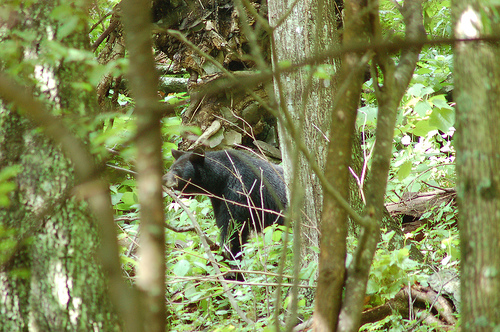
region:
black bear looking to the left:
[158, 137, 293, 267]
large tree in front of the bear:
[160, 3, 276, 149]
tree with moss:
[446, 1, 497, 327]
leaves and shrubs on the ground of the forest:
[10, 170, 455, 320]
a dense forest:
[15, 7, 481, 317]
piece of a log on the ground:
[336, 185, 491, 270]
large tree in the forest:
[267, 0, 424, 296]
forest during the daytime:
[11, 25, 475, 312]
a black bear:
[164, 138, 283, 252]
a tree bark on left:
[1, 20, 91, 330]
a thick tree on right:
[265, 0, 357, 330]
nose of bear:
[164, 172, 179, 187]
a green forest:
[1, 0, 496, 329]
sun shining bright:
[392, 3, 484, 199]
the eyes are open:
[176, 160, 188, 169]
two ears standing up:
[171, 144, 206, 159]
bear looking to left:
[162, 143, 287, 269]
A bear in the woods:
[162, 147, 264, 198]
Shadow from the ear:
[194, 156, 201, 160]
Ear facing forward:
[173, 150, 177, 156]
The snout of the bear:
[165, 174, 172, 183]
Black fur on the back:
[242, 161, 257, 174]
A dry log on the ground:
[404, 199, 423, 209]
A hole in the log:
[405, 216, 411, 221]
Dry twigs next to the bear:
[246, 193, 251, 200]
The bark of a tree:
[468, 273, 497, 329]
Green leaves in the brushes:
[114, 190, 134, 205]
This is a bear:
[147, 136, 304, 278]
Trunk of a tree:
[106, 0, 182, 327]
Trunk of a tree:
[9, 65, 137, 311]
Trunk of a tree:
[344, 72, 399, 325]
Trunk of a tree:
[444, 23, 489, 328]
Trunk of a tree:
[260, 5, 359, 290]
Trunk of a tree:
[313, 39, 359, 299]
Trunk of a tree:
[181, 32, 301, 252]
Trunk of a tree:
[15, 14, 84, 328]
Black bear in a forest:
[158, 146, 293, 256]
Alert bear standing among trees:
[161, 145, 288, 280]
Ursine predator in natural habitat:
[162, 146, 290, 277]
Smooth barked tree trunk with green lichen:
[266, 0, 349, 308]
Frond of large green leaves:
[402, 88, 454, 139]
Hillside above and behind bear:
[111, 0, 271, 147]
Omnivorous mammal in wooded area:
[161, 148, 287, 279]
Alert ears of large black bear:
[169, 147, 206, 162]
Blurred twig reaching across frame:
[2, 30, 498, 267]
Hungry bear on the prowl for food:
[163, 146, 288, 278]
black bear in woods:
[154, 125, 294, 253]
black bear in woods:
[152, 129, 300, 253]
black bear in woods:
[154, 116, 301, 256]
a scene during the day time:
[33, 28, 492, 307]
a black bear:
[118, 111, 381, 271]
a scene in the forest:
[28, 43, 447, 310]